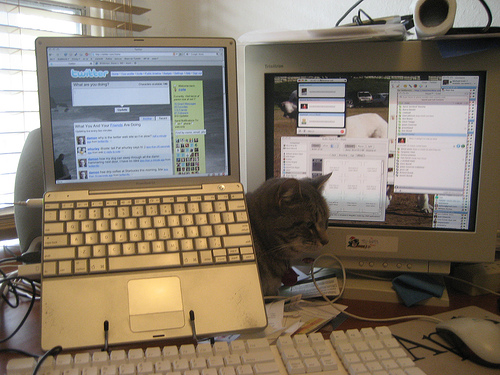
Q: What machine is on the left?
A: Laptop.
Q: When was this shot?
A: Daytime.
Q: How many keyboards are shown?
A: 2.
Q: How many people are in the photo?
A: 0.